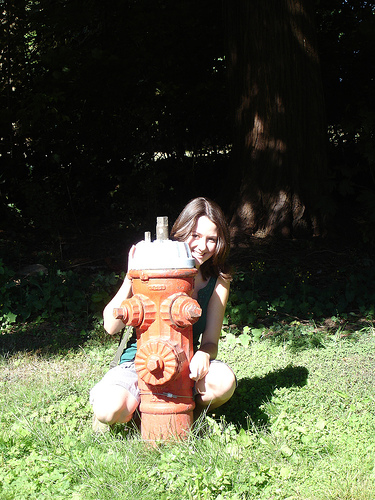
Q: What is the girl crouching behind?
A: A fire hydrant.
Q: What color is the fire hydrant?
A: Red and white.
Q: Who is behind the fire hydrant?
A: A girl.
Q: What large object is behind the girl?
A: Trunk of tree.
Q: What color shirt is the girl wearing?
A: Green.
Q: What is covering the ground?
A: Green grass.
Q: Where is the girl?
A: Behind the fire hydrant.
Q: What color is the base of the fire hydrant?
A: Red.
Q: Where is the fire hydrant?
A: In the grass.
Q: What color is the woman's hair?
A: Brown.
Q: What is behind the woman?
A: A tree.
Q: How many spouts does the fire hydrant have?
A: Three.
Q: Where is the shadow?
A: On the grass.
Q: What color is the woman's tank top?
A: Green.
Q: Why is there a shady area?
A: Lots of big trees.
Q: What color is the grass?
A: Green.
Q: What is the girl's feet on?
A: Green grass.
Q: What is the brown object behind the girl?
A: A tree trunk.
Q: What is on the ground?
A: Grass.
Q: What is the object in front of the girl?
A: A fire hydrant.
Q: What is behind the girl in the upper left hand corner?
A: Vines and bushes.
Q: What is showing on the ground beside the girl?
A: Her shadow.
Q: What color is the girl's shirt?
A: Green.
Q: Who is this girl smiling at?
A: The camera.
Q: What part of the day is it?
A: Day time.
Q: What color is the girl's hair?
A: Brown.